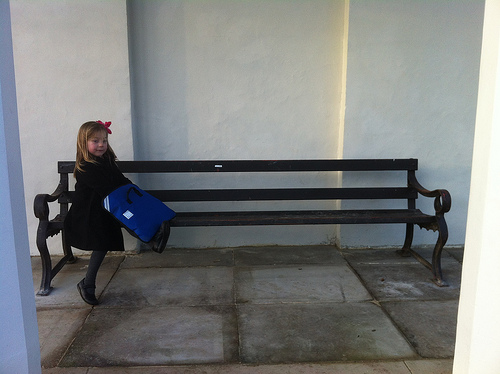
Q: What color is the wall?
A: White.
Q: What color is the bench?
A: Black.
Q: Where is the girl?
A: On the bench.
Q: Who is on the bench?
A: The girl.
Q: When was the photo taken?
A: Daytime.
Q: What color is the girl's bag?
A: Blue.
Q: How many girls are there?
A: One.